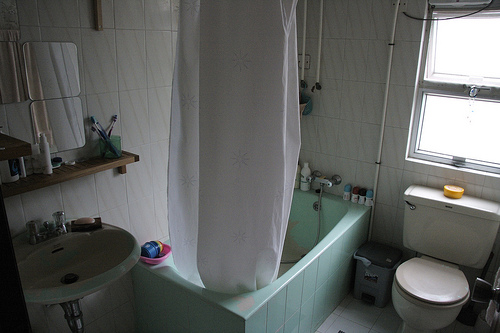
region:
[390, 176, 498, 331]
a ceramic toilet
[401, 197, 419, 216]
the handle to flush a toilet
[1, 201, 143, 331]
a bathroom sink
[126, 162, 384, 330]
a green bathtub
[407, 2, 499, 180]
a bathroom window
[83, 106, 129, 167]
a cup with some toothbrushes inside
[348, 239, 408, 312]
a trash can with a foot level to open the lid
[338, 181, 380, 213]
four bottles are resting on the tub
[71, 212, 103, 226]
a solid bar of soap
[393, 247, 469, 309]
the toilet seat lid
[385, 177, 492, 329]
toilet in a bathroom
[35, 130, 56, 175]
contact solution in front of mirror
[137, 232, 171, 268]
toys in a pink dish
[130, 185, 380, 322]
green bathtub with white curtain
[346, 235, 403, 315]
garbage can next to toilet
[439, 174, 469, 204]
orange container on toilet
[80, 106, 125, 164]
toothbrushes in green container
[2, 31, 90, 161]
mirrors on a wall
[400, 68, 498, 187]
window above the toilet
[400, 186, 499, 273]
white ceramic toilet tank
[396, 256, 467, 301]
white plastic toilet lid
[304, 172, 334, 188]
silver metal faucet on tub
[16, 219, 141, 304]
white ceramic bathroom sink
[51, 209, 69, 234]
silver metal sink handles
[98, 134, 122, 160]
plastic cup on shelf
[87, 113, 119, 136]
tooth brushes in cup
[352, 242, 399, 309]
grey plastic trash can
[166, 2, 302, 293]
white fabric shower curtain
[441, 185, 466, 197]
yellow jar on the back of the toilet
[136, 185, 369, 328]
a green bath tub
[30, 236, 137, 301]
rim of the sink is green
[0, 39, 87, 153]
square mirror panels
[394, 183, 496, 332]
a white toilet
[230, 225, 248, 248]
flower on the shower curtain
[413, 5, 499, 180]
the bathroom window is closed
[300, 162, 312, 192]
a bottle of shampoo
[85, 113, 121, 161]
a cup of toothbrushes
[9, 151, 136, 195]
a small wooden shelf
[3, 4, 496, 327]
interior of residential bathroom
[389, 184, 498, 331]
toilet with closed lid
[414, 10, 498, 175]
light shining through window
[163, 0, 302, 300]
white shower curtain in tub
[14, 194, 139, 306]
oval sink attached to wall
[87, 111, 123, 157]
toothbrushes in green glass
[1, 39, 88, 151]
squares of bathroom mirror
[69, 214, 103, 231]
soap in dish on sink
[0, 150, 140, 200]
wood shelf on wall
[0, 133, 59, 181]
toiletries on wood shelf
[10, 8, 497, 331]
A bathroom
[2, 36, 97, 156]
Square mirrors on the wall.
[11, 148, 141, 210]
A brown wooden shelf.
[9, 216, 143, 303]
An oval white sink.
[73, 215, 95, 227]
A bar of soap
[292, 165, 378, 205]
Shower products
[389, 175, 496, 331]
A white toilet.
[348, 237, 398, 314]
A light grey trashcan with a dark grey lid.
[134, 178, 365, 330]
A light teal bathtub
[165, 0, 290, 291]
A white shower curtain.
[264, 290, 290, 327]
a tile in a wall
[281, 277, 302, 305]
a tile in a wall